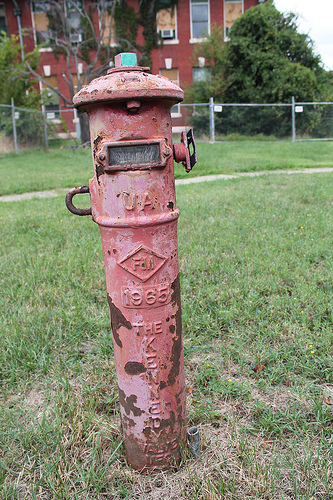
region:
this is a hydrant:
[106, 90, 198, 305]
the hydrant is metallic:
[115, 182, 207, 320]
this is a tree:
[242, 14, 281, 60]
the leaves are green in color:
[244, 43, 270, 60]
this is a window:
[194, 4, 205, 30]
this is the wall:
[178, 47, 189, 64]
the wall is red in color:
[180, 15, 187, 38]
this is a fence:
[228, 104, 302, 133]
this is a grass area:
[220, 204, 308, 304]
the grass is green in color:
[221, 231, 288, 286]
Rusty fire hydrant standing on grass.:
[66, 42, 210, 473]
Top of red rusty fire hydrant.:
[68, 48, 189, 109]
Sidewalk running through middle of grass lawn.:
[210, 156, 330, 184]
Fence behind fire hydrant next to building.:
[198, 95, 332, 153]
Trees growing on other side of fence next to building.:
[201, 8, 331, 138]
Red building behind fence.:
[105, 6, 282, 143]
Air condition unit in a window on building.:
[154, 22, 178, 43]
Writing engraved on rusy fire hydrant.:
[117, 248, 181, 461]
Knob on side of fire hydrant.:
[165, 123, 203, 177]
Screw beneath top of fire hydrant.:
[120, 94, 155, 116]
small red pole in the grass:
[49, 42, 195, 475]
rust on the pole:
[123, 354, 146, 376]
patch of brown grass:
[207, 426, 232, 460]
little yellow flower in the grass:
[228, 376, 233, 384]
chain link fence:
[0, 94, 332, 149]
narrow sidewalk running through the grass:
[1, 156, 331, 204]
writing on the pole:
[129, 321, 178, 467]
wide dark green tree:
[193, 2, 328, 136]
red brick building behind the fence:
[2, 0, 270, 139]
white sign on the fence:
[213, 104, 223, 112]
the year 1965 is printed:
[93, 274, 187, 313]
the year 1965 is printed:
[111, 266, 234, 356]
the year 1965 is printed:
[101, 263, 207, 328]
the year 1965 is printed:
[116, 281, 167, 305]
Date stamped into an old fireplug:
[120, 283, 172, 307]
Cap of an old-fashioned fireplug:
[73, 45, 182, 107]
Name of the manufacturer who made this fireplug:
[130, 318, 178, 467]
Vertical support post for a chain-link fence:
[287, 94, 302, 139]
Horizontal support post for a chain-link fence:
[211, 98, 295, 106]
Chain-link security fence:
[211, 104, 295, 143]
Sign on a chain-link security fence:
[212, 102, 223, 111]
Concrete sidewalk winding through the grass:
[194, 165, 331, 184]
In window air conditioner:
[155, 28, 183, 44]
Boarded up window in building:
[222, 0, 251, 45]